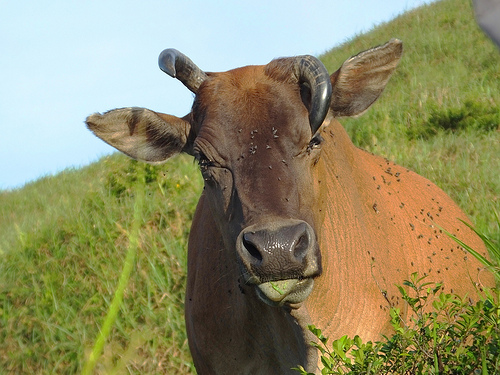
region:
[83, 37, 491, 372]
the bull standing on the grass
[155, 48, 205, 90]
the horn on the bull's head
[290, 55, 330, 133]
the curved horn on the bull's head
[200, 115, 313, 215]
the flies on the bull's face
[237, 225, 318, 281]
the bull's nose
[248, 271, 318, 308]
the bull's mouth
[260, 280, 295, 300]
the bull's tongue sticking out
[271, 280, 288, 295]
the grass on the bull's tongue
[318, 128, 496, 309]
the flies on the side of the bull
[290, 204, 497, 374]
the greenery in front of the bull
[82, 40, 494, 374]
cow sitting in field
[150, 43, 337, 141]
curved horns of cow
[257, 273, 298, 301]
tongue sticking out cow's mouth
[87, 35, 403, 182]
brown ears of cow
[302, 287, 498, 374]
bush in front of cow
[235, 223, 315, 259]
nostrils of brown cow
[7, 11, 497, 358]
grassy hill cow is on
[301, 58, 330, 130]
horn curving into cow's face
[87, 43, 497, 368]
brown cow with tongue sticking out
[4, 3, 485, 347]
bright sunny day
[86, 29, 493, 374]
brown cow chewing food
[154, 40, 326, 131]
black horns of brown cow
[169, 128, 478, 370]
body of brown cow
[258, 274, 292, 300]
grey tongue of brown cow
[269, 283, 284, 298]
green food on cow's tongue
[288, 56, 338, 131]
horn curling into cow's face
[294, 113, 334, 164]
eye horn is curling into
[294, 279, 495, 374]
bush cow is eating from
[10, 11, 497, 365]
grass covering hillside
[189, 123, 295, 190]
flies on cow's face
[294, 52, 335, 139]
Cow's horn is facing down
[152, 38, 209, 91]
Cow's horn is facing up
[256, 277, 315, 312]
Cow has grass on its tongue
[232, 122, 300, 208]
Flies are on the cow's face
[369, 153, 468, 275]
Flies are on the cow's body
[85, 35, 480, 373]
Cow is brown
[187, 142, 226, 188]
Cow has flies in eye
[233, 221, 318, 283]
Cow's snout is wet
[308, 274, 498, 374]
Green shrub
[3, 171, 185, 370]
Grassy landscape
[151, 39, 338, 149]
This bulls horn is messed up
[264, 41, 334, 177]
The horn is growing back into it's head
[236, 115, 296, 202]
Flies are all over it's face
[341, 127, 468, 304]
There are flies all over the bull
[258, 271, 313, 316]
A large green tongue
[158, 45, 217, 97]
This horn is normal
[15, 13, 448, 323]
The bull is standing on a grassy hill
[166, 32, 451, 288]
The bull is brown and covered in flies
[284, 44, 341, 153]
This horn is black and growing wrong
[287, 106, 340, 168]
The horn is in the bulls eye